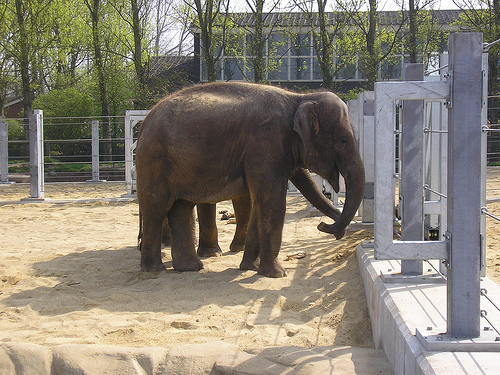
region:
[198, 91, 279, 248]
An elephant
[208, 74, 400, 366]
An elephant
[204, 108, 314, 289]
An elephant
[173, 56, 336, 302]
An elephant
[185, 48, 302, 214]
An elephant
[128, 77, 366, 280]
two big elephants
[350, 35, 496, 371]
white fencing around elephants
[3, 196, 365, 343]
sand covering the ground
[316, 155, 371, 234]
long elephant trunk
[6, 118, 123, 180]
fence made of wires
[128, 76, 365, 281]
elephant is brown color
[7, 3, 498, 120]
tall trees behind enclosure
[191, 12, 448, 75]
many windows on building behind elephants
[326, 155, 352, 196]
elephant's mouth is open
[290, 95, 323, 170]
big floppy elephant ear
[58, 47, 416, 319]
Two wild animals in captivity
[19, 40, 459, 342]
Two elephants in the zoo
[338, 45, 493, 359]
Gray fence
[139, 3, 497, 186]
Far off building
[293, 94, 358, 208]
Big ears of an elephant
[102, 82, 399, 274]
Elephant without tusks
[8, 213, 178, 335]
Sand in the elephant cage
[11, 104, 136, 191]
Gray metal poles and wired fence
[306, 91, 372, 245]
Long trunk of an elephant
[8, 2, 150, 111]
Tall trees behind the fence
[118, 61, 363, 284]
brown elephant in enclosure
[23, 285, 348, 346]
tan dirt in enclosure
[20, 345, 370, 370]
tan rocks in enclosure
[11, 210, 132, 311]
tan dirt in enclosure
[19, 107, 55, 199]
gray fence post in enclosure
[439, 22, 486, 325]
gray fence post in enclosure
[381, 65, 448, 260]
gray fence post in enclosure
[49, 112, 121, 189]
gray fencing wire in enclosure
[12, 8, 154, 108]
brown trees with green leaves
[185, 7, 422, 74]
brown trees with green leaves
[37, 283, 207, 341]
tan dirt in enclosure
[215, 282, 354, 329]
tan dirt in enclosure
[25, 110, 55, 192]
silver post in enclosure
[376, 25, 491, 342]
silver post in enclosure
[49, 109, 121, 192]
silver fencing in enclosure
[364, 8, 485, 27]
brown trees with green leaves